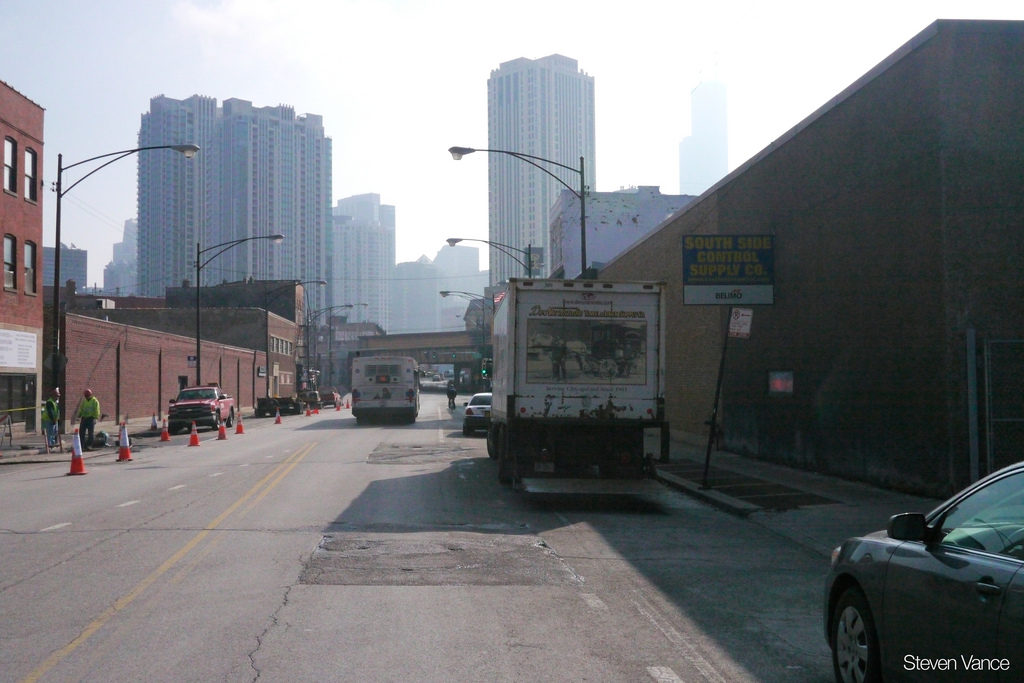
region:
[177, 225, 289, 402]
Light pole behind a red truck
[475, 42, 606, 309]
the tallest building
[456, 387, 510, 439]
white car in front of a white truck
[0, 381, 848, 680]
paved city street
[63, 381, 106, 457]
person in a green shirt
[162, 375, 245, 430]
red pickup truck beside the light pole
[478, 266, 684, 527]
white delivery truck beside signs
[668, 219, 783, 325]
sign attached to side of a building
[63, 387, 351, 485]
row of orange construction cones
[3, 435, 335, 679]
yellow lines on the paveyment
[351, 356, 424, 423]
a white city bus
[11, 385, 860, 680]
two-way street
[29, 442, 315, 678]
double yellow line in the street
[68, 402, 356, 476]
orange traffic cones in the street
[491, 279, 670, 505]
white delivery truck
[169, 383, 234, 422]
red pick-up truck behind orange cones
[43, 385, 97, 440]
two construction workers in yellow vests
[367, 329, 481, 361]
bridges over the road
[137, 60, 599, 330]
tall skyscrapers on the horizon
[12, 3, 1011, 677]
a scene outside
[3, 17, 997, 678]
a scene during the day time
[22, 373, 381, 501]
a row of orange county cones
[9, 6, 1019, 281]
a white sky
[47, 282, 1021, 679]
cars on the road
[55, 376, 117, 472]
a person working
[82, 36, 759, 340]
buildings in the background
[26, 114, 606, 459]
street light poles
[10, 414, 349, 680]
two yellow lines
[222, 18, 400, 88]
grey and white sky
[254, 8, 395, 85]
white clouds in sky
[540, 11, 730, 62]
sky is bright white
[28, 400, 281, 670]
yellow lines on road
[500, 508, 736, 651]
white lines on road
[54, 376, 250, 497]
orange and white cones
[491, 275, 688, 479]
white truck is stopped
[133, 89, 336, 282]
a white multistory building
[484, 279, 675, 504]
a box truck with a black and white picture on the back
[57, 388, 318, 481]
construction cones in the street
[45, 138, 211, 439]
a street light on a pole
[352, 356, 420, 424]
the back of a city bus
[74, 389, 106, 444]
a construction worker wearing a hard hat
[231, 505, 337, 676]
a crack in the asphalt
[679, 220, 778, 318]
blue sigh with yellow lettering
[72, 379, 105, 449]
man wearing green jacket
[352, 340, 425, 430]
white bus with red brakelights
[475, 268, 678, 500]
white and black parked truck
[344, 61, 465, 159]
light in the sky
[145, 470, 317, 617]
yellow lines on ground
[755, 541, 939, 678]
front tire of car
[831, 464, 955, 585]
mirror on side of car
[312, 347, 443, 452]
back of a bus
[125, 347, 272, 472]
car on side of road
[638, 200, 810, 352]
sign above the street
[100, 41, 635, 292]
buildings in the distance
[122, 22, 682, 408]
large sky scrappers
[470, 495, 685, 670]
lines on the road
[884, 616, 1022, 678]
words in white on photo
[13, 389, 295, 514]
orange and white cones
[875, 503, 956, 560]
a mirror on a car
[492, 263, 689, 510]
the back of a truck